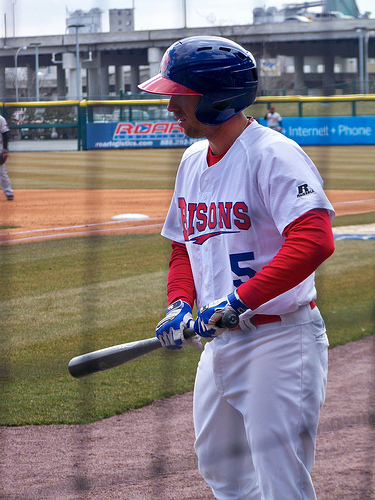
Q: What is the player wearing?
A: White uniform.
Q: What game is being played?
A: Baseball.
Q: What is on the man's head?
A: Helmet.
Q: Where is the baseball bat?
A: Man's hands.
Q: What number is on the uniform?
A: 5.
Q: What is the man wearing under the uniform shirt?
A: Long red sleeves.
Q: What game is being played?
A: Baseball.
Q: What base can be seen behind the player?
A: First base.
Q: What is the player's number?
A: 5.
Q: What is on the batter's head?
A: Blue and red helmet.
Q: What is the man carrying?
A: Baseball bat.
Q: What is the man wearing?
A: Baseball uniform.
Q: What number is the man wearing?
A: Five.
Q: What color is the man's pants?
A: White.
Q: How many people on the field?
A: Three.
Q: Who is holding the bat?
A: The man in front.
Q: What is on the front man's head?
A: A helmet.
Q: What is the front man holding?
A: A bat.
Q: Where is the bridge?
A: Behind the field.